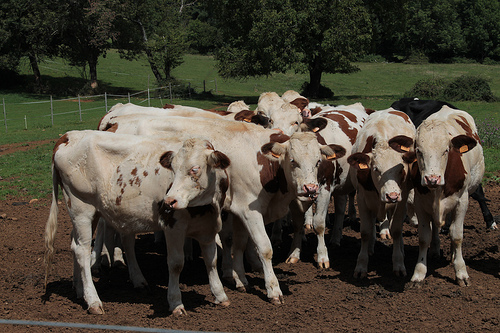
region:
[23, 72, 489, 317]
calves in a group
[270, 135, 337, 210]
orange tags in ears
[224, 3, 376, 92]
green trees in background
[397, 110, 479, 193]
tags in ears for identification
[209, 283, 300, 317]
hooves in dirt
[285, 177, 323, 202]
cow nose for smelling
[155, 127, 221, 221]
white cow face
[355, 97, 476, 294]
brown and white calves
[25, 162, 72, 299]
cow tail in the wind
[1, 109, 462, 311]
small calves waiting in a group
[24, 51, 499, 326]
a herd of cows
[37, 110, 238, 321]
a cow with brown and white spots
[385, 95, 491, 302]
a cow with orange ear tags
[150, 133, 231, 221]
a cow head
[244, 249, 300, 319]
a cows hoof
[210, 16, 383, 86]
a tree with green leaves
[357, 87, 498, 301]
two brown and white cows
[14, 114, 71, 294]
a cows tail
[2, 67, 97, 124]
a metal fence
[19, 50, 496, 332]
six brown and white cows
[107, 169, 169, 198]
Small spots on the cow.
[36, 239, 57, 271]
Tail of the cow.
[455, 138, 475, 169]
Orange tag in the cow's ear.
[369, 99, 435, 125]
Black cow in the background.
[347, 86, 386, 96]
The grass is green.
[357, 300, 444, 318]
The cows are standing in dirt.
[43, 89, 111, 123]
A fence in the pasture.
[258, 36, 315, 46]
The leaves are green.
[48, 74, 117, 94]
Shadow the tree is casting.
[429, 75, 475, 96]
Bushes next to the trees.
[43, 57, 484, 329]
Several white cows with brown spots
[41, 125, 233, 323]
A white cow with brown spots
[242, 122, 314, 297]
A white cow with brown spots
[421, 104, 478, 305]
A white cow with brown spots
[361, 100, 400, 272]
A white cow with brown spots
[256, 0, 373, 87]
A tree with green leaves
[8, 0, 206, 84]
Three trees with green leaves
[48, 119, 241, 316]
A white and brown cow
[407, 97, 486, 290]
A white and brown cow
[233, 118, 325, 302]
A white and brown cow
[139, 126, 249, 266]
Cow looking around.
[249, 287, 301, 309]
Cow hooves in the mud.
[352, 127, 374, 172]
Cow with tag in it's ear.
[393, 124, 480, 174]
Cow with tags in both ears.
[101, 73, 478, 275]
Cows in the pasture.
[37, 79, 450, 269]
A herd of cows.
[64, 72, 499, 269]
A herd of cows in the pasture.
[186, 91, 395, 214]
Cow with a pink nose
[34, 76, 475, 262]
Lots of cows in the fenced in area.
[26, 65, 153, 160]
Green grass